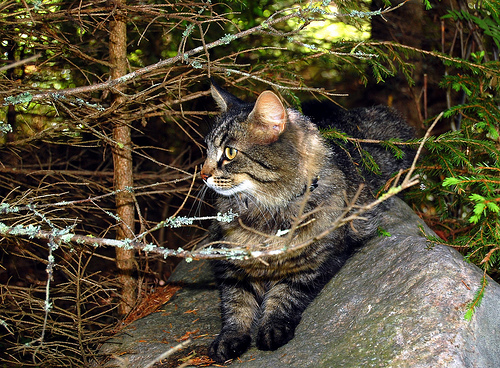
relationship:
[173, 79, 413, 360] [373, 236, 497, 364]
cat laying on rock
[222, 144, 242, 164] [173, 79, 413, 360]
eye of cat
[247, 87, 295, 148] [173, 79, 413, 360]
ear of cat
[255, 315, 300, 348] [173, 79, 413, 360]
paw of cat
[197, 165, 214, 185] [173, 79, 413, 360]
nose of cat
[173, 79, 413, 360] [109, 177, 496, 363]
cat on rock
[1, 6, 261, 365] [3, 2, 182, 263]
branches on a tree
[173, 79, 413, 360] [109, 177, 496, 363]
cat on a rock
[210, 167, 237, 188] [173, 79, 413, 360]
whiskers on a cat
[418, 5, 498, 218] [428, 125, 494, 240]
tree branches with needles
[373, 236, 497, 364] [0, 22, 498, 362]
rock sitting on ground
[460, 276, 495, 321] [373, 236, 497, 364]
pine needles on a rock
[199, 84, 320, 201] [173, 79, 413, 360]
fur on face of cat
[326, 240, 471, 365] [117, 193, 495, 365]
moss growing on rock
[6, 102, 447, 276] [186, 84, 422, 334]
branch in front of cat